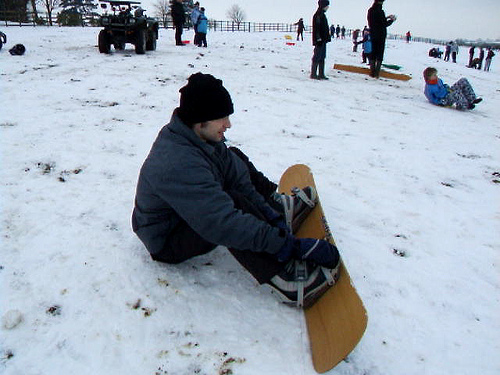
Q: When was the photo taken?
A: Daytime.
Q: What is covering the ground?
A: Snow.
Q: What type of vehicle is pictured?
A: ATV.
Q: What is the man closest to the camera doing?
A: Sitting.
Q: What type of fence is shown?
A: Wood.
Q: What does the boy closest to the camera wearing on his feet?
A: Snowboard.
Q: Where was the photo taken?
A: Snow.